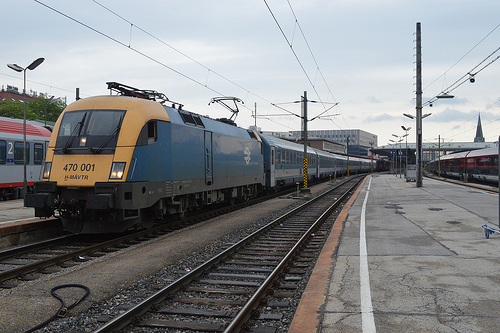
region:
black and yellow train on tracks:
[16, 74, 402, 231]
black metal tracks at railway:
[1, 170, 374, 322]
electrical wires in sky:
[7, 0, 499, 125]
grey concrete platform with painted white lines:
[288, 170, 498, 327]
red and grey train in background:
[3, 110, 58, 188]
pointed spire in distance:
[468, 111, 487, 144]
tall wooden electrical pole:
[406, 19, 431, 200]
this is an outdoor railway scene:
[2, 3, 497, 325]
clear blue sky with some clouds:
[1, 1, 498, 146]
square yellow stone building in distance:
[272, 125, 374, 148]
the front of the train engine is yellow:
[37, 90, 170, 225]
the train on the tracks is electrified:
[20, 15, 385, 231]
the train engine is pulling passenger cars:
[40, 90, 375, 230]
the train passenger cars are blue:
[253, 127, 383, 189]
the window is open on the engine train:
[135, 105, 171, 206]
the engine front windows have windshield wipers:
[48, 106, 123, 162]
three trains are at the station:
[5, 92, 497, 258]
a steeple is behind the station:
[377, 112, 497, 184]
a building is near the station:
[265, 125, 437, 178]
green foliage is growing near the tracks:
[2, 82, 73, 331]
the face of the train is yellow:
[40, 96, 158, 183]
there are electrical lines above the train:
[171, 53, 343, 97]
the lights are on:
[37, 161, 154, 199]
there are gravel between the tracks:
[187, 218, 237, 268]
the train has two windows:
[60, 112, 136, 151]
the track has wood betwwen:
[227, 232, 282, 297]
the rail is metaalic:
[255, 208, 318, 265]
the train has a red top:
[7, 112, 57, 169]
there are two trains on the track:
[7, 113, 180, 224]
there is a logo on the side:
[228, 140, 258, 165]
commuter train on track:
[42, 84, 372, 205]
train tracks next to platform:
[197, 187, 329, 318]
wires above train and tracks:
[158, 50, 339, 124]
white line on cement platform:
[349, 205, 399, 274]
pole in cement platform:
[407, 59, 432, 191]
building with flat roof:
[315, 120, 392, 157]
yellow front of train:
[42, 91, 163, 181]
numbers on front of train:
[58, 156, 105, 174]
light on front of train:
[104, 158, 132, 185]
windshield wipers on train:
[69, 111, 128, 151]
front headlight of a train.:
[107, 159, 127, 184]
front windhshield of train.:
[50, 106, 113, 153]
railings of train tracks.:
[153, 238, 290, 314]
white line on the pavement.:
[353, 182, 393, 329]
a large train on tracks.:
[31, 101, 363, 217]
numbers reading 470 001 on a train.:
[52, 157, 104, 179]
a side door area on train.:
[195, 118, 223, 192]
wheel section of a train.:
[133, 175, 301, 230]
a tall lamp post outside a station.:
[17, 46, 46, 201]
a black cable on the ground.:
[18, 277, 105, 324]